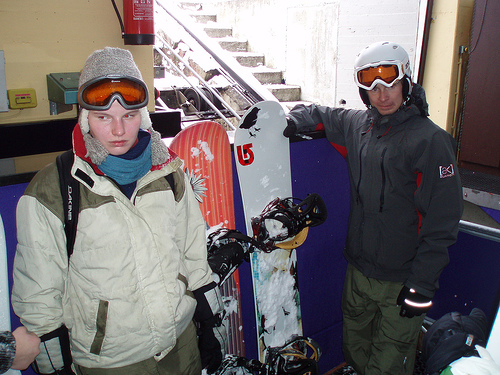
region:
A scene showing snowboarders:
[14, 16, 479, 364]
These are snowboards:
[177, 95, 328, 372]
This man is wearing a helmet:
[351, 37, 422, 127]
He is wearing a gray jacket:
[291, 47, 471, 279]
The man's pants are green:
[329, 254, 425, 374]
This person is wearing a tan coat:
[13, 37, 227, 356]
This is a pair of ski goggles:
[74, 68, 159, 112]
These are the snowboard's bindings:
[249, 192, 328, 372]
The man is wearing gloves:
[394, 281, 436, 324]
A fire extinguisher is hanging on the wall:
[103, 0, 165, 51]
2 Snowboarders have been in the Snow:
[5, 5, 495, 370]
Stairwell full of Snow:
[155, 0, 350, 95]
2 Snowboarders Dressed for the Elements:
[0, 5, 490, 365]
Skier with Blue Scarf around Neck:
[65, 40, 160, 180]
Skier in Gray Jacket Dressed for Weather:
[275, 35, 475, 315]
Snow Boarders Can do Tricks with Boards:
[160, 90, 335, 370]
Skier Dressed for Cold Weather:
[5, 35, 225, 370]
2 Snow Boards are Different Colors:
[165, 100, 330, 370]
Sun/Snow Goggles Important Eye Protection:
[65, 20, 425, 155]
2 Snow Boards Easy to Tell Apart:
[166, 93, 329, 373]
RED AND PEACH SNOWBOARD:
[174, 106, 255, 295]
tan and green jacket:
[30, 170, 220, 367]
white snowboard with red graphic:
[224, 80, 290, 301]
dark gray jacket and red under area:
[317, 92, 448, 272]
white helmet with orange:
[336, 45, 424, 102]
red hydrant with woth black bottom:
[102, 11, 183, 64]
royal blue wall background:
[295, 147, 383, 278]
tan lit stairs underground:
[204, 13, 306, 123]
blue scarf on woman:
[97, 152, 169, 199]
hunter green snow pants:
[347, 283, 419, 365]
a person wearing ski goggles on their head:
[48, 51, 218, 332]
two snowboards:
[152, 105, 382, 374]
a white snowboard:
[231, 105, 341, 373]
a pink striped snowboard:
[158, 109, 265, 354]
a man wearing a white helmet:
[312, 58, 449, 318]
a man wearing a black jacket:
[296, 20, 481, 305]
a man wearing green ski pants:
[340, 53, 425, 367]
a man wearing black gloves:
[263, 57, 441, 323]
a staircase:
[121, 0, 332, 129]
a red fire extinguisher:
[101, 0, 187, 40]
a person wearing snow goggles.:
[69, 49, 168, 163]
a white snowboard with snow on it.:
[229, 81, 327, 373]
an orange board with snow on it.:
[167, 114, 249, 374]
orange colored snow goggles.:
[75, 61, 163, 122]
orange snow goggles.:
[341, 53, 417, 91]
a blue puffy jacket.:
[293, 89, 467, 316]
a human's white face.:
[86, 96, 151, 156]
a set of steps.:
[156, 3, 341, 119]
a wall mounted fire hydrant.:
[115, 0, 154, 42]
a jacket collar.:
[57, 114, 197, 205]